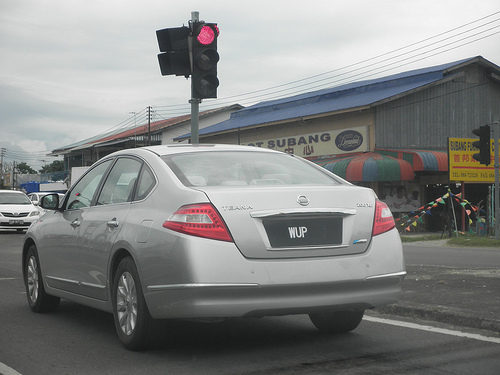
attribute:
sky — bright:
[22, 19, 150, 126]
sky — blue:
[0, 0, 499, 107]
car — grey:
[61, 107, 451, 319]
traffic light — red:
[152, 18, 224, 103]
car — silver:
[20, 129, 437, 343]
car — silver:
[20, 131, 410, 361]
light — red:
[193, 24, 216, 45]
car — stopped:
[16, 105, 417, 350]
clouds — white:
[1, 0, 495, 173]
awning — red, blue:
[424, 152, 449, 169]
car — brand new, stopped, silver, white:
[24, 144, 406, 342]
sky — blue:
[28, 21, 493, 148]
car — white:
[2, 182, 44, 234]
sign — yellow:
[442, 134, 498, 189]